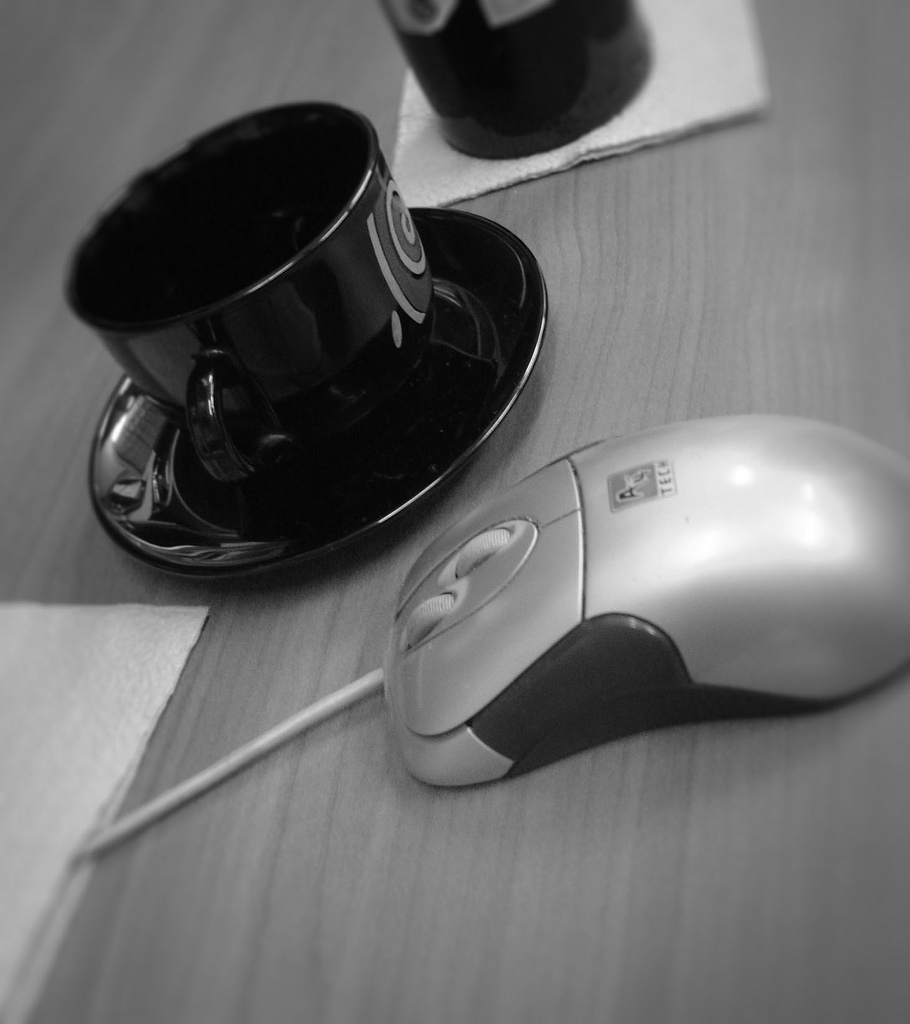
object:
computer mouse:
[384, 413, 910, 791]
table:
[0, 0, 910, 1024]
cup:
[62, 99, 441, 483]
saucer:
[89, 210, 550, 583]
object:
[378, 0, 655, 158]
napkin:
[384, 0, 768, 206]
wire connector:
[83, 668, 388, 857]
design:
[367, 176, 431, 348]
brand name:
[608, 458, 679, 513]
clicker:
[392, 454, 586, 738]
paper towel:
[3, 597, 212, 1024]